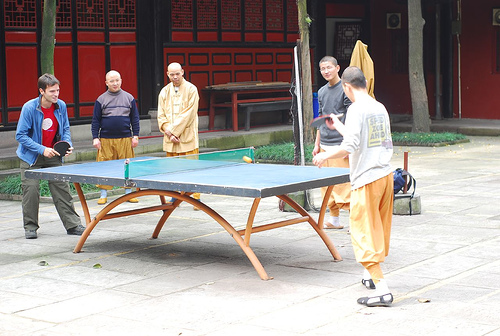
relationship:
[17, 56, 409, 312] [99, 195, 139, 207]
man in sandles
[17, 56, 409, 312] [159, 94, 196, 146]
man has hand